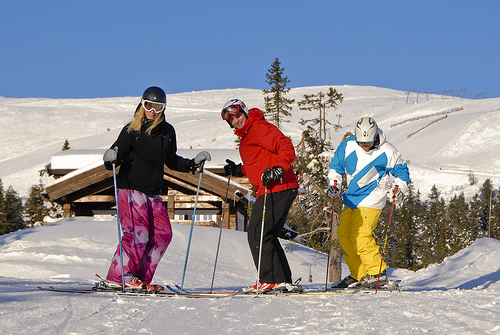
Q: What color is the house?
A: Brown.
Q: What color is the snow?
A: White.